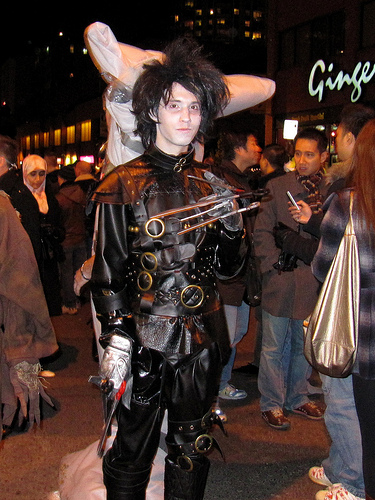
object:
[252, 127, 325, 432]
man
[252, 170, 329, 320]
coat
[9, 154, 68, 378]
woman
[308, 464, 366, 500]
shoes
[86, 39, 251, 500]
guy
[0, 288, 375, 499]
floor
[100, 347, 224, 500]
pants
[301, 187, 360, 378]
bag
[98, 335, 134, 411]
glove